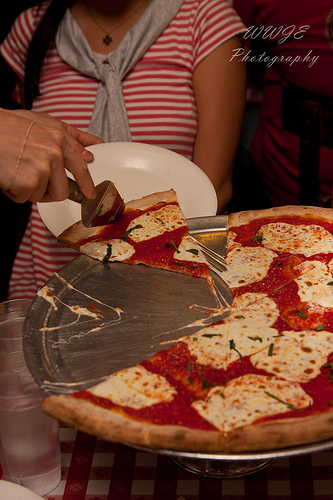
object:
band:
[6, 116, 37, 193]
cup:
[0, 295, 61, 498]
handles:
[46, 167, 85, 205]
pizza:
[57, 189, 209, 278]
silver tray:
[22, 207, 333, 459]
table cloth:
[0, 421, 333, 499]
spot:
[173, 423, 186, 446]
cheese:
[190, 372, 315, 430]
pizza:
[224, 315, 333, 456]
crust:
[44, 392, 333, 452]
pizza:
[226, 204, 333, 315]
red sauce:
[279, 288, 297, 307]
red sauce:
[166, 351, 175, 380]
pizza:
[42, 320, 226, 452]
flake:
[199, 374, 209, 389]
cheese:
[224, 244, 275, 290]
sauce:
[144, 243, 162, 254]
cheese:
[258, 221, 333, 257]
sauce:
[238, 226, 252, 242]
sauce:
[164, 404, 184, 417]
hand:
[0, 110, 98, 205]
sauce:
[317, 379, 330, 404]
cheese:
[86, 361, 177, 409]